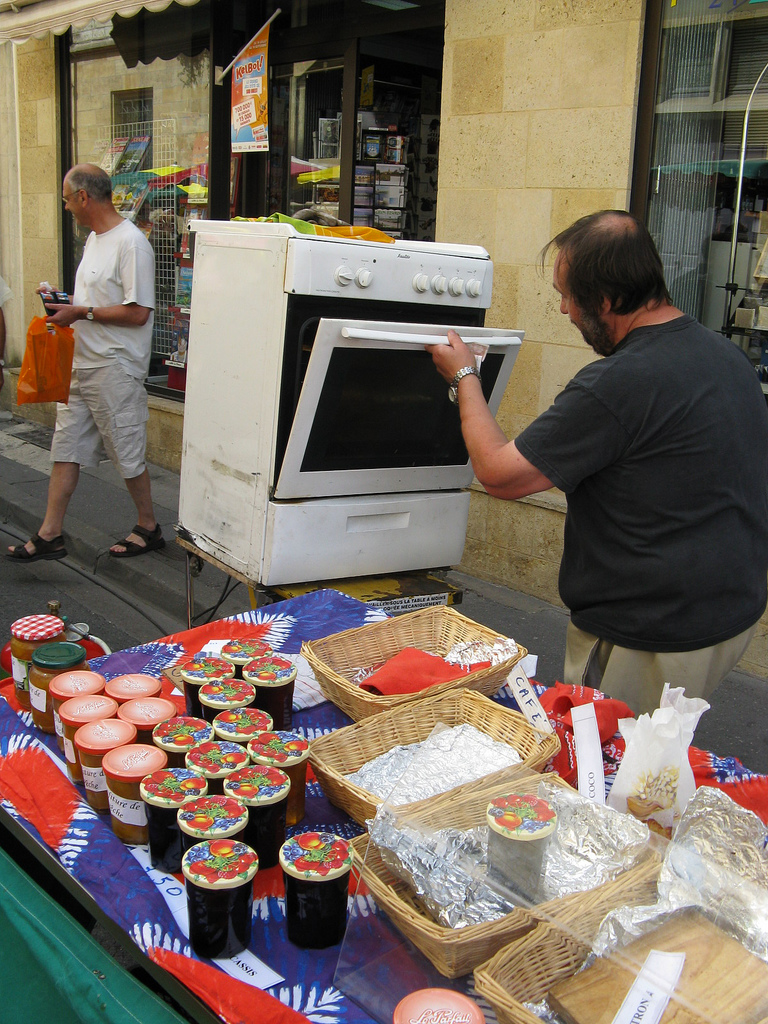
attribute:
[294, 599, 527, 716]
basket —  brown,  wicker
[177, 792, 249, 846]
jar — jelly, glass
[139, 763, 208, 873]
jar — glass, jelly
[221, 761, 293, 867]
jar — jelly, glass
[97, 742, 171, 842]
jar — jelly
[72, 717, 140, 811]
jar — jelly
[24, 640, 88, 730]
jar — jelly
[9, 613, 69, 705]
jar — jelly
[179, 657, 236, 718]
jar — jelly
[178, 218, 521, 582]
stove —  white, white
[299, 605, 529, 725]
basket —  brown,   wicker, wicker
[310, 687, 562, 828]
basket — wicker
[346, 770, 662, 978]
basket — wicker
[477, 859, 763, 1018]
basket — wicker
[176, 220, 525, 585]
oven — white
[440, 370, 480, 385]
wrist — man's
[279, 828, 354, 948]
jar — glass, jelly, jam